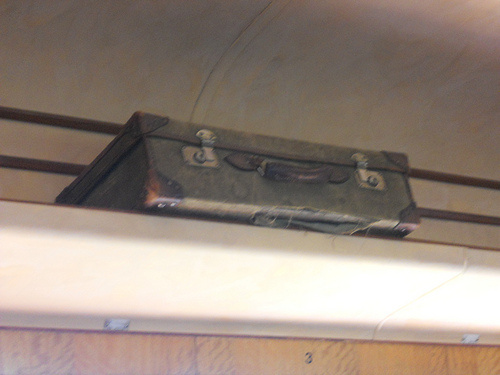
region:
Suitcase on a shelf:
[65, 108, 431, 230]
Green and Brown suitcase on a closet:
[50, 105, 428, 242]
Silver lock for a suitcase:
[185, 130, 231, 174]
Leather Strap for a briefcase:
[227, 142, 354, 196]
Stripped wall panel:
[421, 156, 480, 238]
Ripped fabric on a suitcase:
[255, 202, 385, 244]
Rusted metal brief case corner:
[126, 107, 170, 146]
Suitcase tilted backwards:
[53, 108, 425, 241]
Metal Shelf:
[5, 200, 499, 343]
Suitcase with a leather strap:
[106, 105, 428, 240]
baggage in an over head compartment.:
[45, 54, 415, 264]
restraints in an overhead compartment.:
[0, 83, 498, 225]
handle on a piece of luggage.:
[211, 150, 353, 210]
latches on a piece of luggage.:
[178, 117, 225, 171]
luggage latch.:
[342, 132, 406, 215]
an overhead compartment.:
[0, 189, 498, 351]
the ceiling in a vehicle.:
[3, 8, 498, 199]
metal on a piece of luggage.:
[118, 173, 203, 204]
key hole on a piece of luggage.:
[358, 172, 385, 189]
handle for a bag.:
[220, 144, 333, 208]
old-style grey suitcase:
[50, 90, 425, 240]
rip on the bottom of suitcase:
[230, 190, 395, 240]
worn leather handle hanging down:
[230, 146, 340, 191]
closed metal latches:
[177, 120, 383, 197]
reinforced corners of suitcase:
[130, 100, 190, 212]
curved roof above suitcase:
[40, 12, 467, 237]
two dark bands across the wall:
[2, 100, 494, 235]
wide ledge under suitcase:
[10, 180, 485, 345]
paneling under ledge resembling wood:
[11, 330, 491, 370]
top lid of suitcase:
[122, 102, 417, 179]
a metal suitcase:
[33, 89, 440, 271]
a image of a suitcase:
[2, 17, 482, 368]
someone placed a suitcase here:
[22, 65, 475, 305]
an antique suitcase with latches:
[40, 49, 480, 278]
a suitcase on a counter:
[12, 87, 484, 370]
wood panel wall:
[2, 290, 494, 369]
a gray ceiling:
[2, 4, 499, 229]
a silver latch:
[185, 113, 227, 175]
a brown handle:
[234, 146, 353, 196]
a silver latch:
[345, 128, 383, 200]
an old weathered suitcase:
[45, 94, 448, 254]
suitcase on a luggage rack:
[6, 80, 498, 280]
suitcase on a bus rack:
[11, 10, 492, 369]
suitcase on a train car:
[8, 9, 498, 370]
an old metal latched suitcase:
[51, 81, 444, 283]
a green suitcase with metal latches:
[36, 87, 451, 262]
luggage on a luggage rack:
[14, 17, 489, 370]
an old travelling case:
[13, 8, 490, 369]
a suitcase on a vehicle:
[11, 7, 486, 373]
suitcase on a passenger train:
[13, 7, 495, 368]